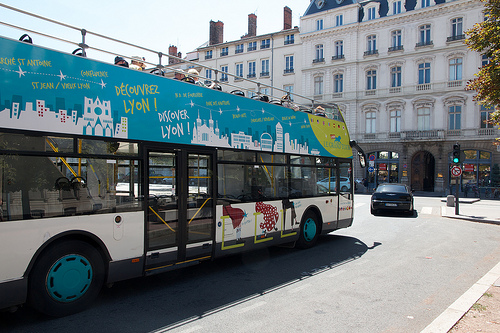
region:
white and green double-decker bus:
[0, 0, 362, 323]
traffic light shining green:
[450, 137, 462, 167]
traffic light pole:
[450, 139, 464, 221]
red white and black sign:
[449, 164, 464, 180]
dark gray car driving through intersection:
[367, 179, 418, 221]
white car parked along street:
[309, 171, 354, 193]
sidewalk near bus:
[406, 227, 498, 330]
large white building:
[102, 6, 498, 193]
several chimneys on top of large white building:
[129, 4, 294, 68]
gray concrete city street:
[2, 185, 497, 331]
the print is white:
[20, 80, 157, 180]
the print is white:
[47, 68, 109, 165]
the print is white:
[76, 44, 178, 205]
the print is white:
[66, 102, 196, 169]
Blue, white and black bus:
[1, 41, 356, 329]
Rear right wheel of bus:
[13, 228, 113, 324]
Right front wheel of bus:
[296, 205, 328, 260]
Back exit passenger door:
[135, 140, 215, 250]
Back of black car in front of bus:
[370, 175, 415, 210]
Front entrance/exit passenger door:
[325, 150, 352, 230]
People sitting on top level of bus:
[111, 50, 341, 120]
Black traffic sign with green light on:
[450, 142, 461, 217]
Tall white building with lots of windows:
[135, 3, 495, 138]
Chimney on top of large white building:
[208, 17, 221, 56]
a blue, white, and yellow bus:
[1, 37, 358, 297]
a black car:
[368, 177, 418, 218]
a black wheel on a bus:
[26, 230, 116, 320]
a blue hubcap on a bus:
[44, 252, 93, 302]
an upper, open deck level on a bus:
[0, 2, 340, 127]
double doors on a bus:
[131, 135, 221, 277]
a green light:
[447, 150, 462, 165]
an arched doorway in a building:
[405, 141, 440, 191]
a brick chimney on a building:
[245, 10, 260, 35]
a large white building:
[290, 0, 497, 185]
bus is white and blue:
[1, 39, 368, 231]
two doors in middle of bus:
[137, 135, 222, 241]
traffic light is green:
[446, 144, 467, 173]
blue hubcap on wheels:
[45, 254, 109, 309]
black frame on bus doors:
[143, 143, 216, 258]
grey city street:
[243, 209, 498, 315]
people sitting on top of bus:
[104, 64, 351, 122]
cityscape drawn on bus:
[11, 83, 156, 145]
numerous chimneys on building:
[163, 1, 308, 61]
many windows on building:
[150, 27, 488, 123]